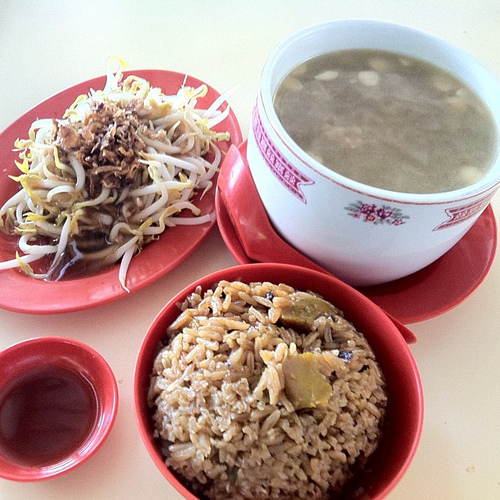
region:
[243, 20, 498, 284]
A large white cup with red designs on it.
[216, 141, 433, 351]
A red spoon for the soup.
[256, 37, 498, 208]
Miso soup with mushrooms in it.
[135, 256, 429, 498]
A large bowl of brown rice.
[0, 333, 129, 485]
A small bowl of sauce for the food.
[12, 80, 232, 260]
A plate of noodles and vegetables.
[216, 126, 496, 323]
A red plate for the bowl of soup.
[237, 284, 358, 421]
Vegetables sitting on top of the brown rice.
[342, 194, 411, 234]
Red flower designs on the bowl.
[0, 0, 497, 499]
A white table with a meal on it.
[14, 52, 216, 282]
red plate with noodles and brown meat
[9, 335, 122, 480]
red bowl with red sauce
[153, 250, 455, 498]
red bowl with brown rice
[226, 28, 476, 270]
white and purple bowl inside red bowl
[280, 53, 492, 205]
brown soup inside white bowl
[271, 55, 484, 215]
brown soup inside white and purple bowl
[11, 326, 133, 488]
red bowl on white table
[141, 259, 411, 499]
red bowl on white table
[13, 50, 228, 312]
red plate on white table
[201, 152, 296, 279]
red spoon in red bowl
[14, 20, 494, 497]
food on a table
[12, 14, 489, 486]
oriental food on a table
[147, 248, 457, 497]
rice in a bowl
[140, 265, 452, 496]
the bowl is red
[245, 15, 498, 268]
soup in a white bowl with red markings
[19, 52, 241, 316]
some kind of sprouts on a plate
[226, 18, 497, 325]
a red spoon is on the dish with the soup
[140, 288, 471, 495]
the rice is light brown in color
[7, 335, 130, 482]
a red sauce in a small dish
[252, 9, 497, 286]
a brothy soup in a bowl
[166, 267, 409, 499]
a bowl of rice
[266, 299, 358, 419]
the rice has meat in it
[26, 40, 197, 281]
bean sprouts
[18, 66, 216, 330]
the plate is red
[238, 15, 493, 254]
a cup of soup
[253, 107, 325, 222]
the cup is white with a dark red design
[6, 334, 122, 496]
a side dish of sauce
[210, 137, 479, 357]
the spoon is red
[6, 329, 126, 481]
the sauce & dish are both red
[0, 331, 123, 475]
soy sauce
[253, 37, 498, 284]
a cup full of soup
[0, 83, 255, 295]
a plate full of white noodles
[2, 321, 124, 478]
a red cup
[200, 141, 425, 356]
a red spoon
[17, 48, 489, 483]
a to-go meal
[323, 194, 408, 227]
a marking on a white cup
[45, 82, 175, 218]
edible toppings on noodles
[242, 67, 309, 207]
red Asian characters on the side of a cup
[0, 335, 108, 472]
brown sauce